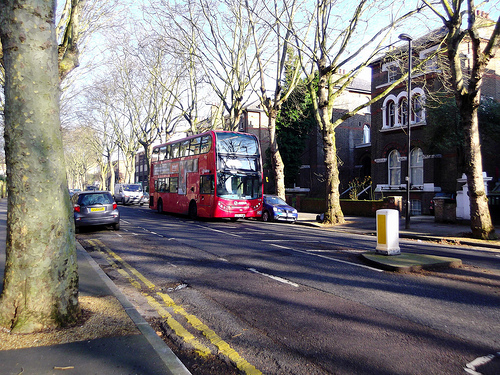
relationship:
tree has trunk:
[4, 0, 88, 339] [3, 42, 85, 332]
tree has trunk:
[423, 0, 499, 232] [460, 138, 492, 239]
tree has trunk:
[291, 1, 358, 225] [323, 155, 346, 224]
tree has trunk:
[245, 2, 304, 218] [266, 145, 294, 199]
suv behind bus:
[116, 184, 143, 205] [150, 132, 267, 220]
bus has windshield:
[150, 132, 267, 220] [218, 173, 262, 200]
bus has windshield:
[150, 132, 267, 220] [216, 132, 258, 156]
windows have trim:
[388, 104, 424, 119] [382, 88, 427, 132]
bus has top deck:
[150, 132, 267, 220] [152, 132, 262, 155]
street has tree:
[74, 189, 499, 369] [4, 0, 88, 339]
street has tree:
[74, 189, 499, 369] [423, 0, 499, 232]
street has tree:
[74, 189, 499, 369] [291, 1, 358, 225]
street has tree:
[74, 189, 499, 369] [245, 2, 304, 218]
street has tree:
[74, 189, 499, 369] [90, 88, 122, 195]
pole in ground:
[377, 208, 400, 257] [362, 249, 463, 270]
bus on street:
[150, 132, 267, 220] [74, 189, 499, 369]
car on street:
[76, 189, 123, 233] [74, 189, 499, 369]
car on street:
[264, 195, 298, 222] [74, 189, 499, 369]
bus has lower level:
[150, 132, 267, 220] [152, 177, 214, 195]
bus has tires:
[150, 132, 267, 220] [157, 200, 165, 215]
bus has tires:
[150, 132, 267, 220] [190, 202, 200, 220]